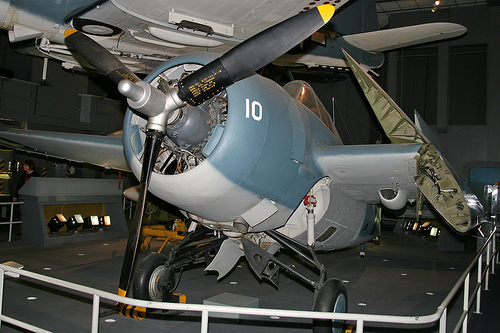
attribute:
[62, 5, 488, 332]
plane — small, on exhibit, railing, displayed, old, illuminated, blue, white, broken, indoor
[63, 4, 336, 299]
propeller — big, black, three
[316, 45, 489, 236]
wing — broken, open, displayed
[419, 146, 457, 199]
wires — exposed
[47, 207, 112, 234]
lights — paneled, four, illuminating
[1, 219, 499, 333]
floor — shiny, slippery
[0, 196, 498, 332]
railing — white, steel, metal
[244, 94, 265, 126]
number — printed, white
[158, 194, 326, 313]
frame — metal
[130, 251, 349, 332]
wheels — black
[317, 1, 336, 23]
tip — yellow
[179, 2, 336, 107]
blade — black, yellow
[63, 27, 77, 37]
tip — yellow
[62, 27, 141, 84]
blade — black, yellow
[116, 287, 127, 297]
tip — yellow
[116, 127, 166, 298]
blade — black, yellow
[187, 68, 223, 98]
print — yellow, tiny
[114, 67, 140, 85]
print — yellow, tiny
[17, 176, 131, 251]
wall — small